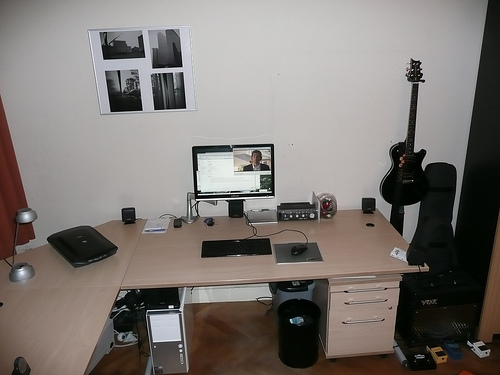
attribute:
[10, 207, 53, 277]
lamp — gray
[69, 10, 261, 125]
frame — large, gray, for picture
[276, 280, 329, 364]
trash bin — black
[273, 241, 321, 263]
mouse pad — silver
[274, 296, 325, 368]
trashcan — black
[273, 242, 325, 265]
mouse pad — gray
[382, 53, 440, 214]
guitar — electric guitar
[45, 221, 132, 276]
scanner — black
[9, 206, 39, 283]
desk lamp — silver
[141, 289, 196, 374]
computer — silver, white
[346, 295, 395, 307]
handle — gray, for drawer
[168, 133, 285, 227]
monitor — large, for computer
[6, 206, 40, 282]
desk lamp — silver, small, for desk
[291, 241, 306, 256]
mouse — black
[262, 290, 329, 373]
can — black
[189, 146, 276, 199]
screen — on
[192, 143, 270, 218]
computer monitor — black, framed, flatscreen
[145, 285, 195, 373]
tower — Apple Mac Pro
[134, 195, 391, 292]
desk — light brown, wooden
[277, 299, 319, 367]
trash can — black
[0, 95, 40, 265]
curtain — red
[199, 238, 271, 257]
keyboard — black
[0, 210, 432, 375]
desk — brown, wooden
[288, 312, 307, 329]
paper — silver and black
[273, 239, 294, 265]
mouse pad — grey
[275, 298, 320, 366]
trashcan — for trash, small, black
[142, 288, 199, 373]
computer tower — gray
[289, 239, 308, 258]
computer mouse — black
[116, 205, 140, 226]
speaker — small, for computer